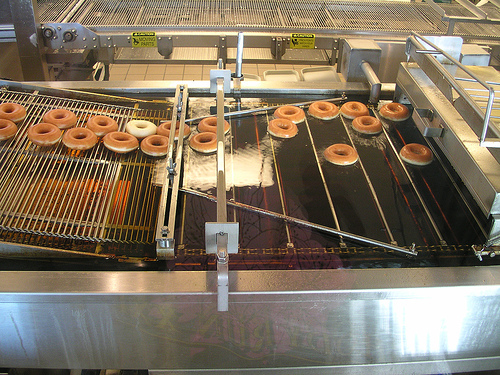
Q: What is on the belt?
A: Donuts.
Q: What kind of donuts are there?
A: Glazed.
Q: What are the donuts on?
A: Conveyor belt.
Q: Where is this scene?
A: Industrial kitchen.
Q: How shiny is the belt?
A: Very shiny.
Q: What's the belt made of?
A: Steel.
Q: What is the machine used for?
A: Baking.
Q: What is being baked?
A: Donuts.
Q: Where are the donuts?
A: Conveyor belt.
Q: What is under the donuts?
A: Grease.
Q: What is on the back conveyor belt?
A: Nothing.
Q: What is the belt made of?
A: Steel.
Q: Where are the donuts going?
A: Into the grease.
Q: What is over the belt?
A: Pole.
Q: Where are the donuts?
A: Fryer.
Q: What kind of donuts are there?
A: Glazed.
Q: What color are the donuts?
A: Brown.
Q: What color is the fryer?
A: Silver.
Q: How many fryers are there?
A: One.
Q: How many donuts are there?
A: Twenty.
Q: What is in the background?
A: Racks.